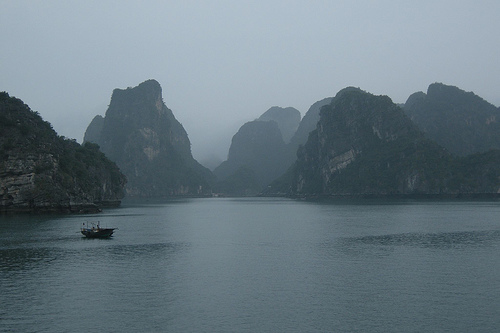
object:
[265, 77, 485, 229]
rock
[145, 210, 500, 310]
lake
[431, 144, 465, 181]
ground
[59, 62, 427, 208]
rock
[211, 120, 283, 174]
hills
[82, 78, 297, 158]
fog layer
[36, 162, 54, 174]
trees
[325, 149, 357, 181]
rocks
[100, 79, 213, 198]
rock formation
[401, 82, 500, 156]
rock formation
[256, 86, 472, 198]
rock formation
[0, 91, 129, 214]
rock formation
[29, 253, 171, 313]
ripples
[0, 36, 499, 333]
scene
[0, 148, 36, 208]
rock face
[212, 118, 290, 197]
rock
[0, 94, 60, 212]
cliff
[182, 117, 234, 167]
mist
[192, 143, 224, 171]
valley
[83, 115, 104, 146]
hills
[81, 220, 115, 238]
boat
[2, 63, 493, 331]
area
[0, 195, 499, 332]
waves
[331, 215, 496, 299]
ripples